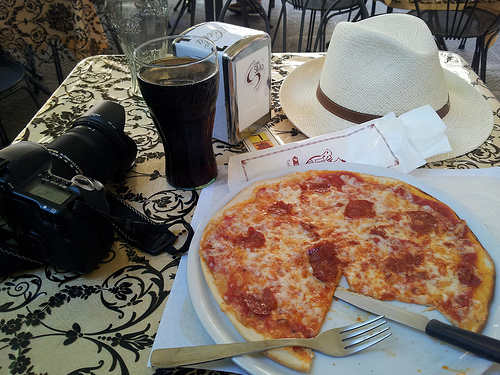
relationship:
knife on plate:
[334, 285, 496, 370] [192, 155, 497, 373]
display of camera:
[27, 179, 71, 206] [9, 83, 141, 283]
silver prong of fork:
[342, 308, 398, 358] [245, 317, 401, 361]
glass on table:
[112, 0, 177, 105] [3, 48, 498, 374]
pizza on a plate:
[210, 178, 493, 368] [192, 155, 497, 373]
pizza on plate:
[199, 168, 495, 368] [362, 342, 466, 374]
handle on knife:
[425, 318, 499, 364] [331, 285, 498, 362]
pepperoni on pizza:
[241, 284, 279, 316] [199, 168, 495, 368]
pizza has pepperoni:
[199, 168, 495, 368] [295, 231, 340, 284]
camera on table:
[0, 104, 150, 279] [3, 48, 498, 374]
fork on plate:
[149, 317, 402, 364] [192, 155, 497, 373]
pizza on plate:
[199, 168, 495, 368] [192, 155, 497, 373]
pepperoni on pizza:
[306, 235, 342, 287] [199, 168, 495, 368]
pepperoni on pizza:
[343, 197, 379, 222] [196, 175, 471, 365]